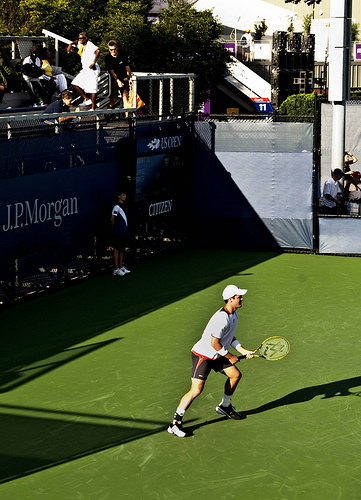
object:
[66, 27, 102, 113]
man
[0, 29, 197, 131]
stands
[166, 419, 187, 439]
tennis shoes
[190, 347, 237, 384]
shorts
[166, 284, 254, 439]
guy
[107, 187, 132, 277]
guy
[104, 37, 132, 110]
guy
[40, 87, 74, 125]
guy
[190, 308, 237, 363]
shirt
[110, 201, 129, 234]
shirt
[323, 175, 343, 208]
shirt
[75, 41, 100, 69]
shirt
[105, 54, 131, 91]
shirt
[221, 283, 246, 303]
cap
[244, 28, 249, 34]
cap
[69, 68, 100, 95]
shorts